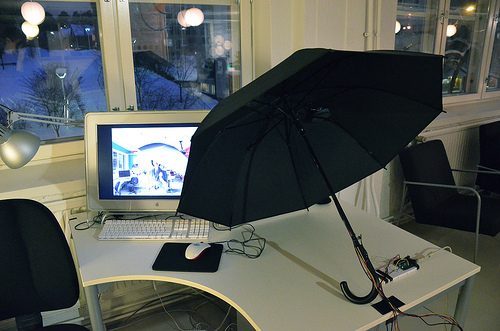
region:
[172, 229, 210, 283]
White apple mouse on the desk.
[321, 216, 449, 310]
the umbrella has wires attached to its handle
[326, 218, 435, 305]
the umbrella is part of an experiment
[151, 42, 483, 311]
the umbrella is black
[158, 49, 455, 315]
the umbrella is opened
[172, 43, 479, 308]
the umbrella is on the desk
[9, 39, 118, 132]
it is snowing outside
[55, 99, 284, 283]
there is a computer on the desk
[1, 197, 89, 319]
an office chair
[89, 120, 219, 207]
a computer screen on the desk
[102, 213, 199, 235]
a keyboard on the desk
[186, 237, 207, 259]
a white computer mouse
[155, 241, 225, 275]
a black mouse pad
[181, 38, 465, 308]
a black umbrella on the desk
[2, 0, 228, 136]
a window behind the desk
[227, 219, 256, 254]
a cord on the desk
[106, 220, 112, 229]
key on a keyboard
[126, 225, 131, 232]
key on a keyboard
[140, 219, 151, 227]
key on a keyboard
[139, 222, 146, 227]
key on a keyboard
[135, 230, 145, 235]
key on a keyboard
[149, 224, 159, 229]
key on a keyboard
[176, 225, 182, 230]
key on a keyboard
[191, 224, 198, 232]
key on a keyboard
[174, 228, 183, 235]
key on a keyboard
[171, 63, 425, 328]
an open umbrella on the desk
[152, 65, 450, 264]
an open black umbrella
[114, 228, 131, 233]
a button on the keyboard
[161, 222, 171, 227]
a button on the keyboard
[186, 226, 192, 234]
a button on the keyboard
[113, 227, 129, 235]
a button on the keyboard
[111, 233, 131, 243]
a button on the keyboard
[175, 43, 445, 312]
a open black umbrella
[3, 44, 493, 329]
an umbrella on a desk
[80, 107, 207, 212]
a white computer monitor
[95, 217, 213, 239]
a white computer keyboard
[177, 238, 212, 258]
a white computer mouse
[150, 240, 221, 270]
a black computer mouse pad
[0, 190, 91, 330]
a black computer chair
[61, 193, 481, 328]
a white computer desk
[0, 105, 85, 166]
a silver desk lamp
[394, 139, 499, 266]
black chair with silver arm rest